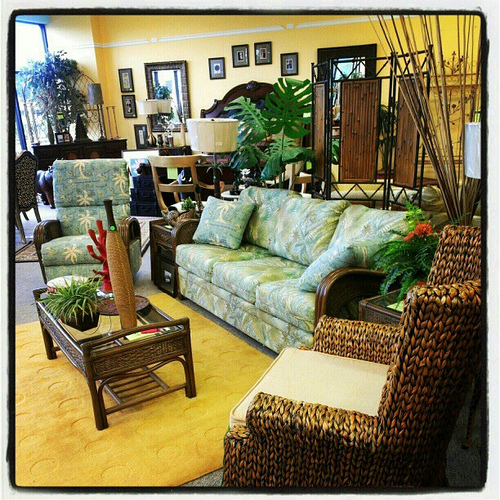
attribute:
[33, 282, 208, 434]
table — brown, wicker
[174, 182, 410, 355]
couch — green, tropical, printed, patterened, three-seater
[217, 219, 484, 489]
wicker furniture — woven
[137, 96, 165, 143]
lamp — white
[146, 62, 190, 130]
mirror — large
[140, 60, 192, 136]
mirror — large, brown trimmed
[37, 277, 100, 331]
plant — potted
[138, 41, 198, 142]
mirror — woven wicker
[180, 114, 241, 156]
lamp shade — round, white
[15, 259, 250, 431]
table — woven, wicker, rattan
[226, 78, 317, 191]
plant — fake, tall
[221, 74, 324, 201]
palm — potted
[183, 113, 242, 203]
lamp — beige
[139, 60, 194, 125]
mirror — rectangular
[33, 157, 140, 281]
chair — palm tree patterened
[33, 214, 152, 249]
arms — brown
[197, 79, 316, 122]
headboard — dark, wood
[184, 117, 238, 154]
shade — white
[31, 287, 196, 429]
coffee table — wood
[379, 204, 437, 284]
plant — green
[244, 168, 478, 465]
chair — green, patterened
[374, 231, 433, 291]
plant — pot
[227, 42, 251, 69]
picture — square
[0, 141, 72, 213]
chair — black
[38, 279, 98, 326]
plant — green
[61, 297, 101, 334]
planter — dark brown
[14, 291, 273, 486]
rug — yellow, bright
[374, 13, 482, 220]
sticks — long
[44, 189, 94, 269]
chair — printed, green, tropical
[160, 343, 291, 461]
rug — thick, yellow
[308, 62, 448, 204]
bamboo screen — black, metal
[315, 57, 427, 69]
frame — black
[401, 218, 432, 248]
flower — fake